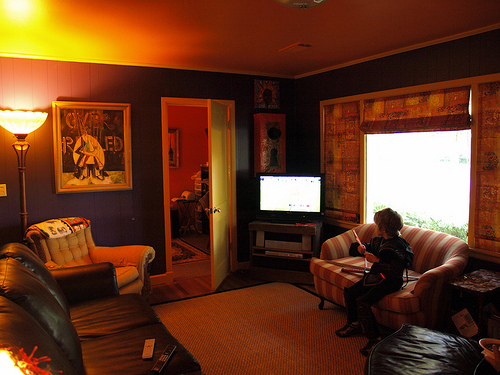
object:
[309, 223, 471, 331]
couch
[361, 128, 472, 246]
window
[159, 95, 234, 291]
door way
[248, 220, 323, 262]
stand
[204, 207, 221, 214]
knob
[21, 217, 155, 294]
furniture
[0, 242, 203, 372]
brown hair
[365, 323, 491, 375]
foot stool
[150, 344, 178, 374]
remote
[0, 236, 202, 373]
leather sofa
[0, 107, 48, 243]
floor lamp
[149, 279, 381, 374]
area rug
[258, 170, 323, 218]
tv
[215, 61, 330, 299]
corner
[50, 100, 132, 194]
picture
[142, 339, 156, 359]
remote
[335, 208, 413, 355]
boy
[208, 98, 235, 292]
door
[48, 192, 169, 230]
wall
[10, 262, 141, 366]
furniture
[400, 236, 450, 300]
furniture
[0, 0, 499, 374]
room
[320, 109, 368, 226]
wall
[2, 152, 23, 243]
wall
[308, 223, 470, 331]
chair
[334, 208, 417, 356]
child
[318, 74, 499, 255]
curtains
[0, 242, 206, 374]
couch